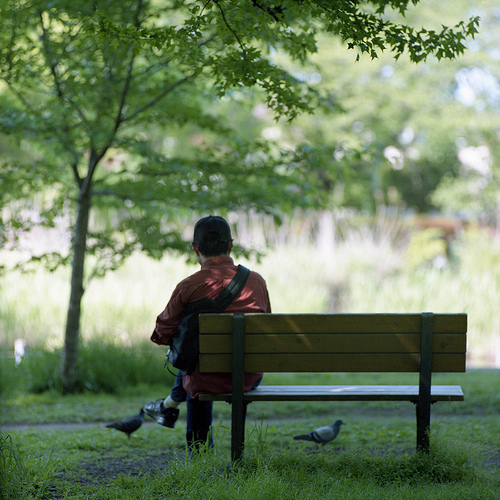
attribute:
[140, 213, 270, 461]
person — alone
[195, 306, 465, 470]
bench — wooden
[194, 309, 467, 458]
bench — wooden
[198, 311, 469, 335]
piece — wood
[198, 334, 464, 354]
piece — wood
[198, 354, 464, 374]
piece — wood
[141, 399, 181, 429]
shoe — black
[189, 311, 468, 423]
bench — wooden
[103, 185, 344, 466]
man — seated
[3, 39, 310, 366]
tree — green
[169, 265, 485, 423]
bench — wooden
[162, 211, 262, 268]
cap — dark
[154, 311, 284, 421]
backpack — dark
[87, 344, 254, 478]
shoe — dark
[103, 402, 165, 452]
pidgeon — walking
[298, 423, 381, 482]
pidgeon — walking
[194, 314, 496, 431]
bench — wooden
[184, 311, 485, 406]
bench — wooden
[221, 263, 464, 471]
bench — wooden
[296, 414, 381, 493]
bird — small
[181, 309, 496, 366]
panels — wooden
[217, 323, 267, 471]
support — metal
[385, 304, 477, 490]
support — metal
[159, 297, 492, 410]
seat — wooden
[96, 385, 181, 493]
bird — black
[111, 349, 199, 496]
shoe — black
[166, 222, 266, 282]
hat — black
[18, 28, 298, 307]
tree — green